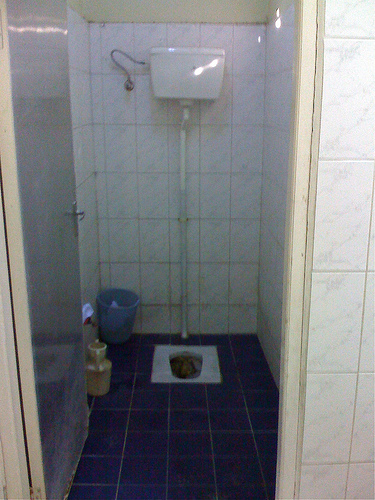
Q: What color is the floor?
A: Blue.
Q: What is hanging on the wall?
A: Toilet tank.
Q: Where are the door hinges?
A: Left side of door.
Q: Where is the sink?
A: There isn't any sink.